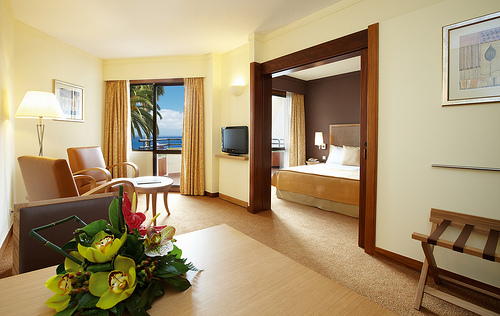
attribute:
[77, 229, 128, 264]
flower — yellow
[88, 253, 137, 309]
flower — yellow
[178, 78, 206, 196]
curtains — yellow, beige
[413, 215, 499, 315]
stand — wooden, wood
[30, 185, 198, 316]
plants — plastic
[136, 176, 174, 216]
table — round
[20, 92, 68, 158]
lamp — lite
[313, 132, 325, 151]
lamp — white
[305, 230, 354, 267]
carpet — fuzzy, tan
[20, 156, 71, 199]
chair — brown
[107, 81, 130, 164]
cutain — open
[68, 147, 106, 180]
cushions — leather